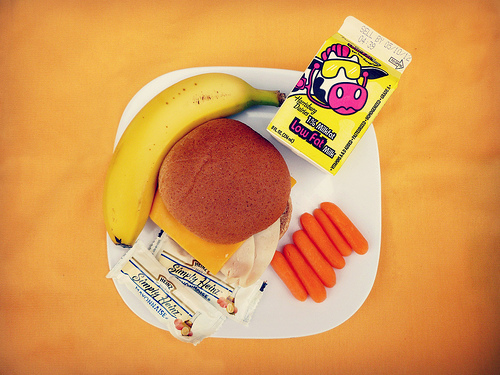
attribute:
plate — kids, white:
[108, 64, 382, 341]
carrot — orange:
[318, 202, 370, 257]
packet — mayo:
[107, 239, 227, 347]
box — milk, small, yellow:
[265, 15, 412, 178]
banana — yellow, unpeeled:
[106, 71, 286, 249]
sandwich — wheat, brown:
[156, 120, 293, 286]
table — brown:
[1, 2, 500, 373]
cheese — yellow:
[149, 190, 246, 276]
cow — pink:
[287, 44, 392, 117]